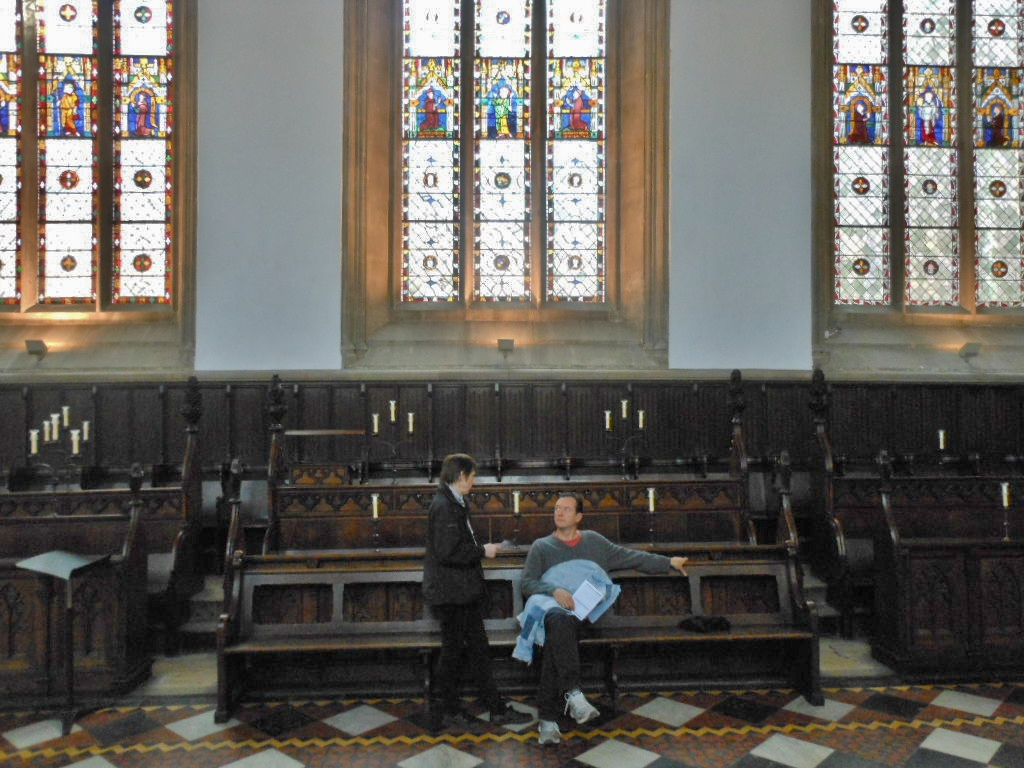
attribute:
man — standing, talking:
[420, 443, 509, 729]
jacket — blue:
[513, 579, 581, 666]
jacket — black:
[423, 485, 490, 613]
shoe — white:
[539, 718, 565, 744]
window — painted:
[347, 0, 674, 370]